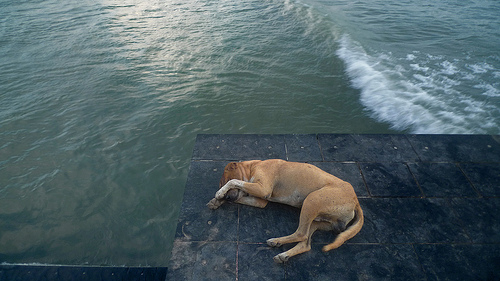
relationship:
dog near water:
[200, 160, 367, 262] [0, 62, 179, 272]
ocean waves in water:
[0, 0, 500, 268] [138, 54, 344, 125]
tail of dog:
[322, 204, 368, 251] [207, 154, 378, 261]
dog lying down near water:
[205, 159, 364, 263] [40, 4, 406, 127]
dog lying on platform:
[200, 160, 367, 262] [165, 128, 498, 279]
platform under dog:
[165, 128, 498, 279] [210, 157, 366, 260]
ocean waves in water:
[0, 0, 500, 268] [6, 4, 489, 134]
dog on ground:
[200, 160, 367, 262] [167, 127, 496, 277]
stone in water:
[173, 128, 494, 276] [4, 6, 495, 266]